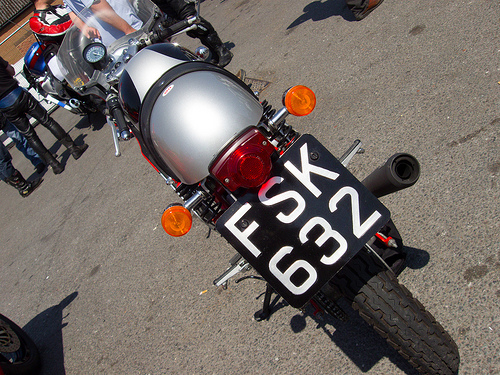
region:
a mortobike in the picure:
[71, 24, 411, 361]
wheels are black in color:
[376, 262, 412, 373]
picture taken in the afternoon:
[152, 147, 437, 327]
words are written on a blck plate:
[250, 166, 352, 333]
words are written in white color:
[247, 170, 370, 285]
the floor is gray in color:
[91, 227, 195, 369]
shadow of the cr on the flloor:
[5, 301, 74, 371]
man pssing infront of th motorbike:
[63, 0, 160, 54]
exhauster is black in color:
[362, 149, 416, 186]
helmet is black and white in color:
[98, 26, 221, 112]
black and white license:
[182, 155, 407, 330]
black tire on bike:
[339, 247, 434, 350]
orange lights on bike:
[127, 49, 320, 256]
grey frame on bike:
[125, 77, 259, 177]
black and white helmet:
[115, 39, 180, 121]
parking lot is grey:
[353, 62, 495, 152]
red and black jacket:
[37, 9, 60, 51]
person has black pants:
[12, 64, 64, 196]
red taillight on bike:
[216, 114, 264, 206]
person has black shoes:
[41, 137, 86, 200]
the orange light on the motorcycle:
[161, 205, 192, 237]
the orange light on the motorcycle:
[286, 84, 316, 116]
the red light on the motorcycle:
[207, 124, 274, 192]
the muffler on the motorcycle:
[364, 152, 421, 197]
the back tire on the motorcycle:
[329, 248, 461, 373]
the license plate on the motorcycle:
[213, 133, 390, 308]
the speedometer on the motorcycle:
[82, 42, 108, 70]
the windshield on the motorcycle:
[57, 0, 164, 95]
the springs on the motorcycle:
[173, 100, 300, 227]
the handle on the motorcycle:
[106, 96, 131, 140]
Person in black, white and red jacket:
[30, 1, 77, 61]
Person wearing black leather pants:
[1, 56, 88, 178]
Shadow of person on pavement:
[284, 0, 363, 27]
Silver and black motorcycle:
[47, 2, 459, 374]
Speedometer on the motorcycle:
[80, 38, 108, 65]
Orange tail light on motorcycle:
[159, 201, 193, 238]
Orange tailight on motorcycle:
[282, 82, 317, 119]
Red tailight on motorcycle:
[208, 126, 275, 193]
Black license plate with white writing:
[214, 133, 391, 310]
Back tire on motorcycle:
[331, 249, 459, 374]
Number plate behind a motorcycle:
[210, 130, 393, 307]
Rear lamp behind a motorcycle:
[155, 82, 319, 239]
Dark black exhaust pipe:
[350, 148, 423, 203]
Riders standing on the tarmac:
[0, 1, 235, 197]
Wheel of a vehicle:
[0, 310, 50, 372]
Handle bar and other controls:
[50, 0, 205, 155]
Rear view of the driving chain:
[305, 285, 350, 325]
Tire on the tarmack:
[330, 250, 462, 372]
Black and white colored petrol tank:
[106, 37, 206, 124]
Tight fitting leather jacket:
[1, 88, 89, 177]